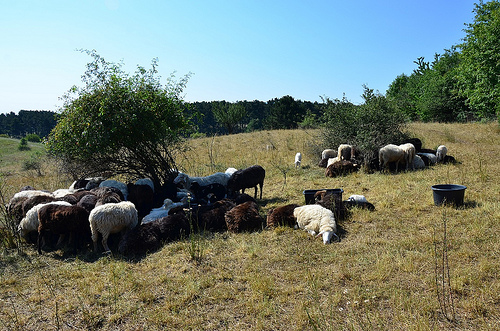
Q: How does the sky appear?
A: Blue and clear.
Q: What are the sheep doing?
A: Grazing.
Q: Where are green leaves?
A: On the trees.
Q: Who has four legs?
A: One sheep.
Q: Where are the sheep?
A: On a grassy field.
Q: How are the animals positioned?
A: Laying down and standing.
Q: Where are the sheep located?
A: In a field.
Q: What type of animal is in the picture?
A: Sheep.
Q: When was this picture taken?
A: Daytime.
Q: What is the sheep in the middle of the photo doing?
A: Sleeping.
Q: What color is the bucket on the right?
A: Black.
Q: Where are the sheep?
A: In a pasture.